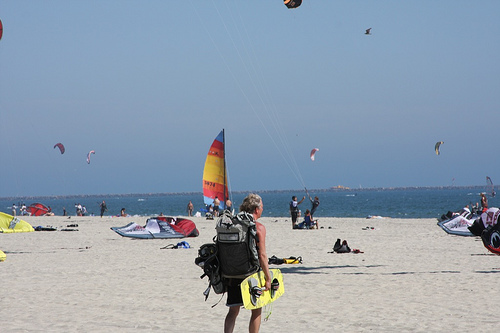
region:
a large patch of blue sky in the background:
[0, 0, 499, 197]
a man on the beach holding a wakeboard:
[195, 192, 285, 332]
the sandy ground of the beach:
[0, 215, 499, 332]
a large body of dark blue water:
[0, 187, 499, 218]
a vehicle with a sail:
[201, 127, 229, 214]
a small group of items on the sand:
[327, 237, 364, 253]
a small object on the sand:
[160, 240, 195, 249]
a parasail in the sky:
[309, 146, 319, 161]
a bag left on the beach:
[267, 255, 302, 265]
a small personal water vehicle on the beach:
[110, 215, 200, 238]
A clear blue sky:
[59, 27, 276, 101]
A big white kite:
[303, 143, 327, 168]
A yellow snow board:
[238, 263, 290, 308]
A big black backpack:
[214, 207, 262, 279]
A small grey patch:
[212, 213, 260, 243]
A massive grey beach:
[44, 263, 180, 323]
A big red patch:
[28, 202, 51, 218]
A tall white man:
[207, 190, 274, 330]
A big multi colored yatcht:
[196, 125, 237, 214]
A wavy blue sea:
[353, 190, 441, 210]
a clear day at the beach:
[19, 21, 492, 318]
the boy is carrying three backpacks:
[198, 195, 290, 329]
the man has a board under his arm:
[238, 194, 288, 314]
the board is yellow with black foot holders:
[239, 269, 286, 309]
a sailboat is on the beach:
[193, 125, 234, 212]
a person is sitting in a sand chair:
[300, 206, 320, 231]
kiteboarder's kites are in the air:
[35, 111, 455, 176]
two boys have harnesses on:
[285, 185, 322, 215]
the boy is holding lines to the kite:
[202, 40, 323, 216]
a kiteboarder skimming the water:
[339, 185, 364, 203]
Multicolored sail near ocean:
[196, 128, 236, 206]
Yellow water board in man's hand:
[240, 267, 282, 309]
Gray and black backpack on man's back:
[210, 212, 257, 281]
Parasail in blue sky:
[434, 139, 444, 155]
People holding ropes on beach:
[288, 192, 319, 227]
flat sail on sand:
[110, 217, 185, 240]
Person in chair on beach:
[305, 208, 320, 228]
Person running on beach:
[97, 198, 107, 218]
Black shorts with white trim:
[223, 280, 243, 306]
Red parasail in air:
[53, 138, 68, 155]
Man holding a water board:
[223, 252, 303, 305]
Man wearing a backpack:
[203, 208, 268, 298]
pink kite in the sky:
[302, 145, 324, 169]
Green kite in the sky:
[416, 120, 462, 162]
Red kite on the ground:
[18, 198, 53, 227]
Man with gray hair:
[231, 183, 276, 230]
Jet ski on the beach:
[106, 200, 210, 257]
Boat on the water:
[335, 185, 369, 205]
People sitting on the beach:
[328, 228, 370, 270]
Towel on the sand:
[156, 234, 197, 256]